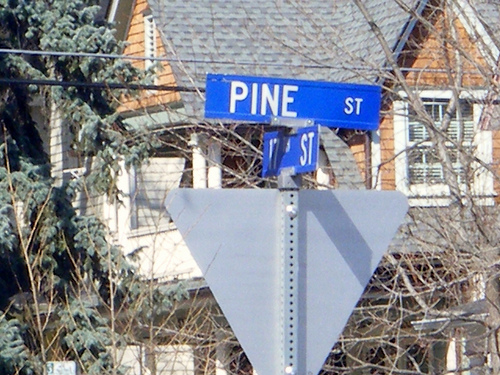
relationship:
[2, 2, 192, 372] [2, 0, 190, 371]
leaves on tree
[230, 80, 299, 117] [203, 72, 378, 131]
pine on sign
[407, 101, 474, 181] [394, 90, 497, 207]
mini blinds on window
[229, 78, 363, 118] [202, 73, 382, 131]
text on signs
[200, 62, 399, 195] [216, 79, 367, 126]
signs with text print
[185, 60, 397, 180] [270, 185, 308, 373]
signs on pole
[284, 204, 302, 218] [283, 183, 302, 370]
screw on pole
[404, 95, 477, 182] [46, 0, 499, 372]
window on house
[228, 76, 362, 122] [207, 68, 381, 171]
writing on sign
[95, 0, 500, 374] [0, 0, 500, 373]
tree next to house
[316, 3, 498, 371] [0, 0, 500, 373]
tree next to house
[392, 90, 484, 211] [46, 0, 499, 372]
window on house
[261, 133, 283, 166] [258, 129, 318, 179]
number on sign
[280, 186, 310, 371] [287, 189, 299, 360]
pole with holes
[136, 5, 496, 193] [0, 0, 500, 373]
roof of house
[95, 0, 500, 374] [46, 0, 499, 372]
tree near house